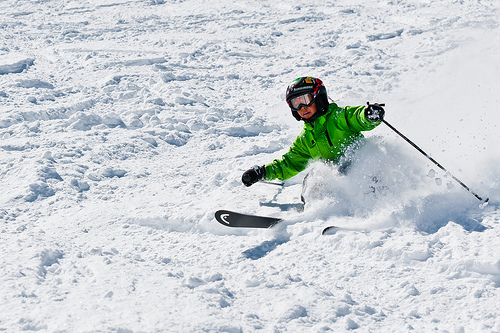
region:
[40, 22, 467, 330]
this guy is skiing on the snow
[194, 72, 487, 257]
he is being buried by the snow while he skies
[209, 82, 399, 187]
he is wearing green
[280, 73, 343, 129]
he has on goggles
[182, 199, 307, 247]
one of his skiis is sticking out of the snow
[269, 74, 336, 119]
he is wearing a helmet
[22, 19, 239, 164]
the snow is messy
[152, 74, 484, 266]
he is taking slopes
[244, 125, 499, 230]
his ski poles help him to balance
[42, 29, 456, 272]
the sun is shining over the snow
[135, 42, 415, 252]
the person is skiing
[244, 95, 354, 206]
the jacket is green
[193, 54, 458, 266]
a skier coming down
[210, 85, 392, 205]
green jacket on skier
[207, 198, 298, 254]
black bottom of ski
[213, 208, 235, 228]
white symbol on bottom of ski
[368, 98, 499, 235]
a black pole in hand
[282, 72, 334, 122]
a colorful helmet on head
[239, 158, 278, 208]
black gloves on hands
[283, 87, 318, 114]
black goggles on face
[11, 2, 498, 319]
snow covered ground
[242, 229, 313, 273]
shadow from ski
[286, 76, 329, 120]
black red and green helmet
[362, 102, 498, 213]
black pole of skateboarder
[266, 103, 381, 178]
green jacket of skateboarder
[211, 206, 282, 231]
black ski buried on snow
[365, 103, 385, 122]
black glove in right hand holding black pole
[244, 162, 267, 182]
black glove in right hand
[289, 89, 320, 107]
glasses on the face of snowboarder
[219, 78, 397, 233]
snowboarder buried on snow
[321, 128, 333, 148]
black zip in green jacket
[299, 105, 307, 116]
little nose of snowboarder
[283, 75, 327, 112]
ski helmet on head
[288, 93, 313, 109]
black goggles on head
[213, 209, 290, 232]
long black ski in snow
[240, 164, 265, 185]
black padded winter gloves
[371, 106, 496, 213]
black metal ski pole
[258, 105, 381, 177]
green padded winter jacket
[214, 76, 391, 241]
man standing on skis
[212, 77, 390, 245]
man falling on snow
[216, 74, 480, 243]
man skiing down hill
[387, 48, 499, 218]
snow thrown up in air